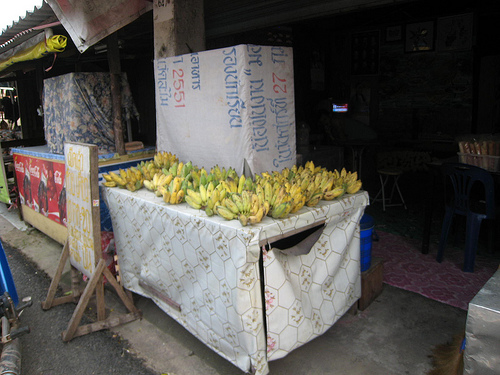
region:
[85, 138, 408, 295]
table of short bananas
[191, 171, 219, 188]
green unripe bananas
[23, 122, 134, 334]
wooden sale sign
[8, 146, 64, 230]
red coca cola poster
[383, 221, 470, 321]
pink floral carpet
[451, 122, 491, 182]
basket of bread wrapped in platic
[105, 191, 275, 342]
white and gold honey comb table cloth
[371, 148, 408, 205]
old white folding chair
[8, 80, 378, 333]
Empty Market in Thailand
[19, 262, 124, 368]
rough black top road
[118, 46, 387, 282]
bananas on a table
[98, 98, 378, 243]
the bananas are in bunches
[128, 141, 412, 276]
bananas are yellow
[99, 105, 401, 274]
the bananas are ripe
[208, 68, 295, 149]
the font is asian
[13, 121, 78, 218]
signs for coca-cola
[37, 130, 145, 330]
a price sign for bananas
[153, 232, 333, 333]
the table cloth is white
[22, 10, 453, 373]
bananas at an outdoor market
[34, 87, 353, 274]
tables at the market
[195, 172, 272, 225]
a bushel of yellowish green bananas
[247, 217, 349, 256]
a piece of the cloth is ripped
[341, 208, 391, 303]
a blue pail on top of a wooden box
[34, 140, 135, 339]
a sign made of wood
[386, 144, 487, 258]
blue chair in the dark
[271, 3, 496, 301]
a bar that is not opened yet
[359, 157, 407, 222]
a small stool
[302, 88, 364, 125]
an electric device is on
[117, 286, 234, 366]
the floor is concrete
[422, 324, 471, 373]
the bottom of a broom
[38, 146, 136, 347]
wooden sign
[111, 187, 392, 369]
white table cloth with an octagon pattern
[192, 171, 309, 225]
bunches of yellow and green bananas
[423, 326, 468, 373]
liquid on the ground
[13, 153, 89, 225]
red Coca-Cola sign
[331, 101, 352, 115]
some sort of electronic monitor lighting up the dark background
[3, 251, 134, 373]
dark blue pavement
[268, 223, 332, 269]
black hole in the tablecloth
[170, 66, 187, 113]
sideways red lettering that says "2551"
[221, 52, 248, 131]
sideways blue lettering in all caps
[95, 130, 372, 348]
bananas at display table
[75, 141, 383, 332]
several bananas at display table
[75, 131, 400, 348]
many bananas at display table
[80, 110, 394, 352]
multiple bananas at display table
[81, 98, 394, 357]
lots of bananas at display table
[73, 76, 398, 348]
edible bananas at display table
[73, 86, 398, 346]
tasty bananas at display table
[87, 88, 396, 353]
delicious bananas at display table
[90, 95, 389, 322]
plenty bananas at display table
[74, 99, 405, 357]
bananas at display table in view